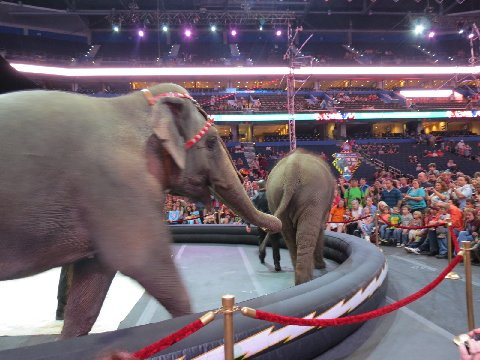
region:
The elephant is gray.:
[1, 80, 279, 345]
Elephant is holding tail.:
[0, 80, 343, 334]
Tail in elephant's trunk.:
[31, 70, 325, 325]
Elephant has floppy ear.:
[87, 51, 293, 291]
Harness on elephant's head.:
[81, 60, 305, 280]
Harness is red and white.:
[128, 59, 231, 198]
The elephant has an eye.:
[127, 68, 292, 260]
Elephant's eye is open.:
[140, 74, 290, 255]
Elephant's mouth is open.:
[81, 59, 293, 279]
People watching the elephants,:
[86, 91, 478, 312]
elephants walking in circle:
[7, 52, 353, 352]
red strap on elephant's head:
[125, 71, 234, 163]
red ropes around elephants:
[77, 132, 478, 353]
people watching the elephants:
[214, 126, 469, 246]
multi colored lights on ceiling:
[89, 7, 324, 90]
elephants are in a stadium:
[0, 4, 474, 358]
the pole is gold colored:
[209, 282, 247, 356]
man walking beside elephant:
[246, 166, 298, 268]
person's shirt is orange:
[330, 200, 348, 224]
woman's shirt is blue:
[405, 180, 429, 212]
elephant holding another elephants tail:
[40, 47, 360, 315]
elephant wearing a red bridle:
[105, 60, 237, 205]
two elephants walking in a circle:
[12, 49, 397, 354]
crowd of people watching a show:
[290, 113, 467, 260]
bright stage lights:
[108, 6, 448, 59]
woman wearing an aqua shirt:
[402, 172, 432, 223]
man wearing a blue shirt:
[376, 173, 407, 227]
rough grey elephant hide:
[24, 132, 110, 213]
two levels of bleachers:
[247, 85, 458, 190]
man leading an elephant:
[240, 162, 310, 287]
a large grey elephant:
[0, 81, 279, 337]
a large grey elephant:
[263, 146, 337, 281]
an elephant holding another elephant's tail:
[3, 83, 340, 337]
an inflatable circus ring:
[2, 214, 388, 355]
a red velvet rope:
[250, 248, 463, 325]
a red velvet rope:
[117, 312, 208, 358]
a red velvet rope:
[444, 221, 462, 252]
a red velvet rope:
[376, 210, 443, 231]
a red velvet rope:
[328, 207, 367, 224]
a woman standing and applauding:
[402, 175, 423, 207]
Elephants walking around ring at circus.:
[2, 64, 339, 319]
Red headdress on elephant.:
[138, 82, 215, 188]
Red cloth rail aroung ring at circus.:
[210, 228, 478, 358]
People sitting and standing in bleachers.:
[378, 156, 479, 261]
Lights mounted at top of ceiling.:
[108, 11, 298, 41]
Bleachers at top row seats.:
[233, 84, 403, 127]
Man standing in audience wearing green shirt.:
[342, 172, 366, 214]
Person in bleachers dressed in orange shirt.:
[441, 197, 465, 232]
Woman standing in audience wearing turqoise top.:
[404, 175, 432, 216]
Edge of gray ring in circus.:
[330, 227, 398, 352]